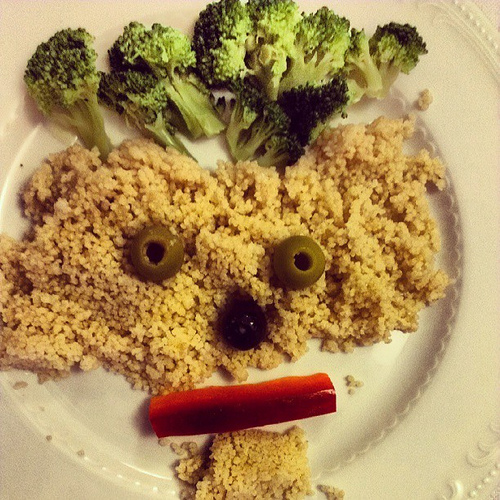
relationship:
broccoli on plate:
[54, 34, 389, 133] [9, 56, 480, 498]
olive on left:
[125, 203, 191, 268] [87, 169, 205, 267]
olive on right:
[272, 205, 341, 301] [282, 199, 398, 328]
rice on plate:
[50, 126, 397, 351] [9, 56, 480, 498]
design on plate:
[355, 415, 428, 459] [9, 56, 480, 498]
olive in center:
[224, 294, 276, 339] [209, 96, 461, 278]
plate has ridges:
[9, 56, 480, 498] [424, 167, 485, 339]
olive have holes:
[125, 219, 188, 284] [149, 234, 168, 271]